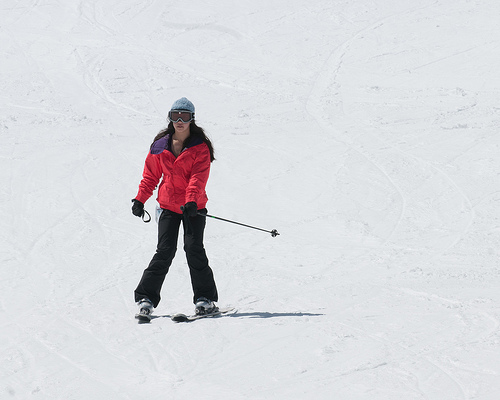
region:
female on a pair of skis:
[118, 96, 286, 324]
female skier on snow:
[118, 94, 287, 326]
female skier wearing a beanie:
[109, 95, 283, 326]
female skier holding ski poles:
[127, 90, 291, 330]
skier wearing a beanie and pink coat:
[125, 92, 283, 325]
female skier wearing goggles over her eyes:
[125, 95, 285, 326]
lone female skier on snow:
[120, 94, 285, 324]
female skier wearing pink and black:
[124, 94, 285, 329]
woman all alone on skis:
[125, 92, 290, 327]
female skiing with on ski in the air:
[121, 95, 283, 327]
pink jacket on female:
[130, 130, 220, 215]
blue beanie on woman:
[167, 98, 194, 109]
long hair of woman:
[197, 118, 211, 140]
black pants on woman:
[134, 206, 219, 305]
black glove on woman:
[125, 195, 149, 216]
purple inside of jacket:
[150, 131, 171, 148]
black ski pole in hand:
[192, 203, 304, 245]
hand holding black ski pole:
[175, 204, 295, 254]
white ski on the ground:
[165, 300, 255, 327]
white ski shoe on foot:
[190, 298, 220, 313]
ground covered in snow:
[322, 185, 444, 377]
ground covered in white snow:
[330, 240, 445, 375]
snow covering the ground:
[237, 202, 454, 393]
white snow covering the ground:
[314, 264, 420, 395]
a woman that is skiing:
[97, 102, 358, 389]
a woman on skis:
[57, 92, 314, 394]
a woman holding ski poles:
[99, 94, 356, 386]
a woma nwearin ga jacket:
[92, 83, 199, 338]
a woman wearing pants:
[91, 85, 276, 387]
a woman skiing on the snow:
[44, 95, 321, 398]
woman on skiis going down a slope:
[115, 90, 285, 325]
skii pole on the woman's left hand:
[182, 202, 283, 242]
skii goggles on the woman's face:
[167, 108, 197, 123]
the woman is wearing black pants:
[140, 209, 220, 304]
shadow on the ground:
[147, 305, 320, 324]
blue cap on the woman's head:
[168, 96, 194, 113]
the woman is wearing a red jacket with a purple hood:
[129, 128, 217, 218]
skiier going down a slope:
[125, 91, 283, 323]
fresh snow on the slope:
[5, 4, 495, 397]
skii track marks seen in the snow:
[307, 67, 483, 387]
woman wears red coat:
[114, 82, 246, 328]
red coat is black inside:
[129, 125, 219, 215]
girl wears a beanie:
[145, 87, 220, 180]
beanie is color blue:
[159, 90, 204, 125]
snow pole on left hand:
[171, 197, 281, 245]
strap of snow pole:
[126, 197, 154, 227]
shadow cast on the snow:
[154, 290, 332, 335]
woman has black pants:
[122, 90, 232, 325]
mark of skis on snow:
[285, 28, 382, 156]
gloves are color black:
[126, 194, 200, 219]